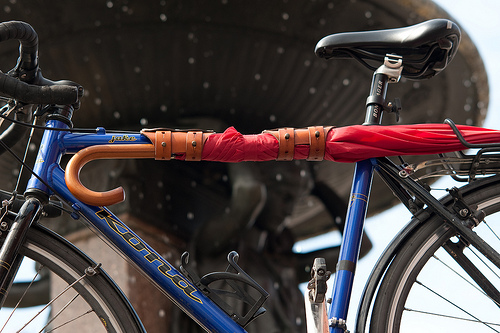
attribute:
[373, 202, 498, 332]
spokes — silver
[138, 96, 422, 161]
umbrella — red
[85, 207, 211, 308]
sticker — black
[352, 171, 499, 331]
wheel — black, back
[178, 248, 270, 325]
holder — black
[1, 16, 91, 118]
handle — black, curved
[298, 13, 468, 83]
seat — black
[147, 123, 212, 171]
straps — brown, leather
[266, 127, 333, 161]
straps — leather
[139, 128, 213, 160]
straps — leather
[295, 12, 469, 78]
bicycle seat — black, leather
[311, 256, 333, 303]
peddle — black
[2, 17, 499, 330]
bike — mountain bike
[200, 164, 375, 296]
statue — female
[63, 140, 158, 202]
handle — wooden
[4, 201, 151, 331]
wheel — black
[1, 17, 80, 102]
handle bar — black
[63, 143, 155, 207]
holder — wooden, brown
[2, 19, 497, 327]
bicycle — blue, black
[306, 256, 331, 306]
pedal — black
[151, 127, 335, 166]
belt — orange